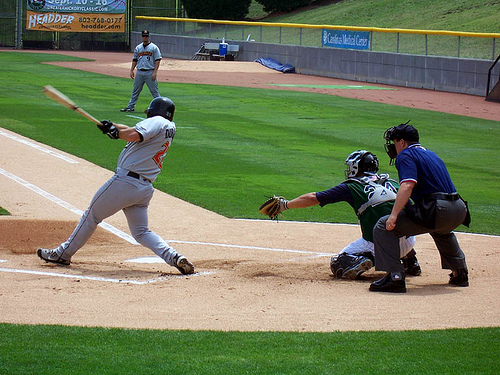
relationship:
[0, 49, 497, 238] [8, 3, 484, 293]
grass on field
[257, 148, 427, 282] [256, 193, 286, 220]
man wearing glove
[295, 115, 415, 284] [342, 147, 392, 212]
man wearing protective gear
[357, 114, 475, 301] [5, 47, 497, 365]
umpire watching pitch